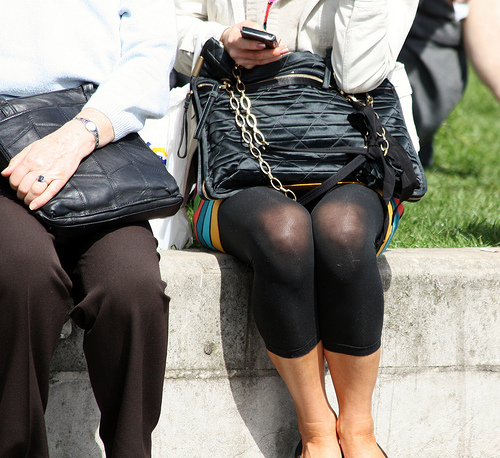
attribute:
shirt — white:
[176, 3, 408, 105]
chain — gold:
[215, 73, 390, 191]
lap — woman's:
[0, 187, 160, 280]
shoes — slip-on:
[286, 436, 388, 457]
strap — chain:
[222, 84, 409, 204]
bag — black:
[174, 49, 433, 201]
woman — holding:
[4, 0, 188, 457]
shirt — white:
[0, 0, 190, 138]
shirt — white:
[142, 2, 415, 102]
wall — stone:
[5, 250, 498, 454]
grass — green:
[384, 59, 499, 244]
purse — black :
[178, 62, 309, 211]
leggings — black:
[221, 180, 385, 358]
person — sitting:
[177, 3, 444, 457]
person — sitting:
[3, 0, 183, 457]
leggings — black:
[215, 186, 393, 382]